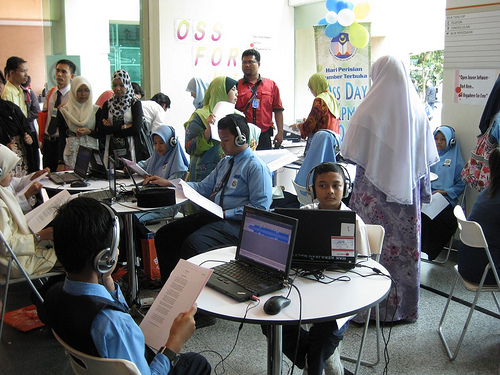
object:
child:
[301, 161, 372, 254]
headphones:
[305, 162, 351, 200]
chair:
[351, 223, 387, 264]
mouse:
[263, 295, 291, 315]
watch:
[158, 346, 177, 360]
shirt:
[58, 278, 171, 375]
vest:
[31, 287, 129, 362]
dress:
[347, 155, 432, 324]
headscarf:
[144, 125, 189, 183]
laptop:
[205, 205, 297, 302]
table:
[186, 242, 393, 324]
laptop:
[282, 210, 358, 267]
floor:
[346, 295, 483, 375]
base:
[329, 341, 382, 367]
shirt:
[229, 77, 286, 135]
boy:
[41, 197, 212, 375]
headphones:
[94, 199, 121, 277]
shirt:
[191, 151, 274, 219]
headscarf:
[340, 55, 441, 205]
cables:
[324, 273, 351, 284]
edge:
[336, 279, 393, 311]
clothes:
[46, 280, 172, 372]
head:
[52, 195, 121, 278]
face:
[315, 171, 343, 204]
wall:
[164, 3, 295, 129]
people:
[152, 112, 272, 281]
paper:
[454, 71, 492, 100]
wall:
[443, 9, 489, 151]